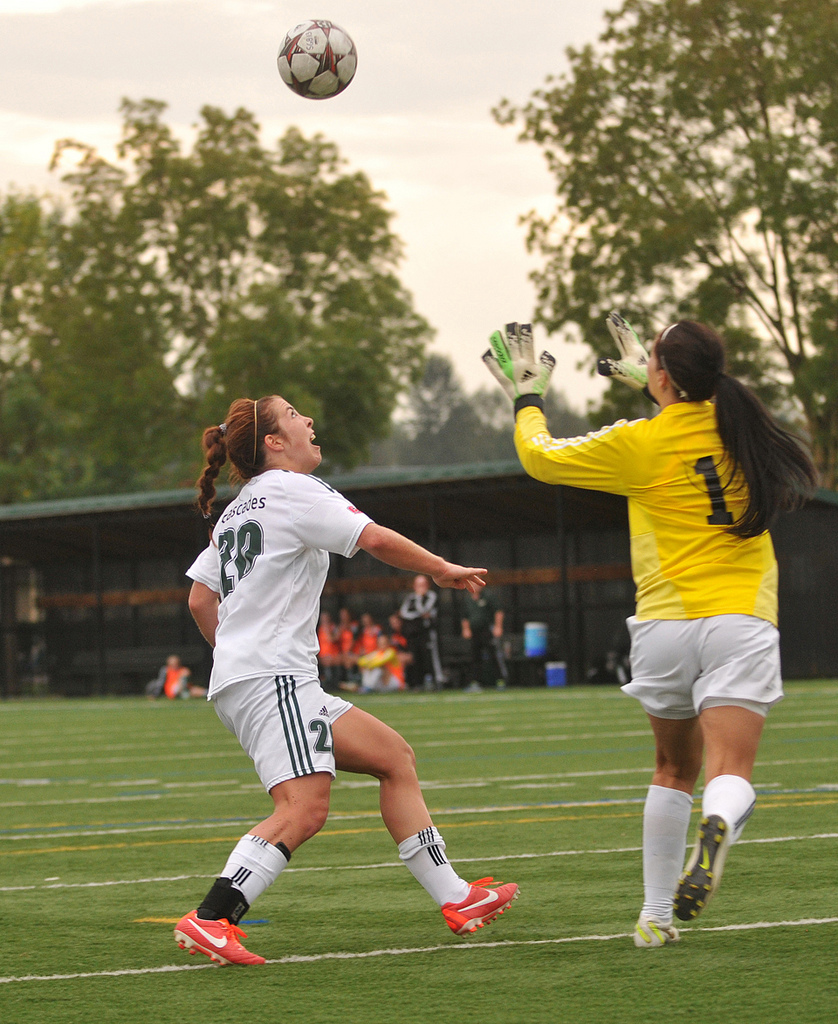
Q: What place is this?
A: It is a field.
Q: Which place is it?
A: It is a field.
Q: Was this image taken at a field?
A: Yes, it was taken in a field.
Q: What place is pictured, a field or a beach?
A: It is a field.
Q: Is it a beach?
A: No, it is a field.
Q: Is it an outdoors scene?
A: Yes, it is outdoors.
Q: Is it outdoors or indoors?
A: It is outdoors.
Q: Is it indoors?
A: No, it is outdoors.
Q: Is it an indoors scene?
A: No, it is outdoors.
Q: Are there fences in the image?
A: No, there are no fences.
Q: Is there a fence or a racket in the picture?
A: No, there are no fences or rackets.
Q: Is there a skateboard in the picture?
A: No, there are no skateboards.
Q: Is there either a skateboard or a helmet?
A: No, there are no skateboards or helmets.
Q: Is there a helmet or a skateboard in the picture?
A: No, there are no skateboards or helmets.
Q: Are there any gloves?
A: Yes, there are gloves.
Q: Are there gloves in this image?
A: Yes, there are gloves.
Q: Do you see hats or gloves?
A: Yes, there are gloves.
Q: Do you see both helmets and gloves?
A: No, there are gloves but no helmets.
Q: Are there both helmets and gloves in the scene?
A: No, there are gloves but no helmets.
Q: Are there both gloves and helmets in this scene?
A: No, there are gloves but no helmets.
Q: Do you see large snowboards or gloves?
A: Yes, there are large gloves.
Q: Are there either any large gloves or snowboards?
A: Yes, there are large gloves.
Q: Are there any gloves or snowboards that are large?
A: Yes, the gloves are large.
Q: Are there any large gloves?
A: Yes, there are large gloves.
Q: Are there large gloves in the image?
A: Yes, there are large gloves.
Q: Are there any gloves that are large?
A: Yes, there are gloves that are large.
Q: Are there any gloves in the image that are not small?
A: Yes, there are large gloves.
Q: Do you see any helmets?
A: No, there are no helmets.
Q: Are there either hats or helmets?
A: No, there are no helmets or hats.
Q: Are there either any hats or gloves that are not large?
A: No, there are gloves but they are large.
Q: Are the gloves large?
A: Yes, the gloves are large.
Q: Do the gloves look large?
A: Yes, the gloves are large.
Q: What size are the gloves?
A: The gloves are large.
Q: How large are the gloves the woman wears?
A: The gloves are large.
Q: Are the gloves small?
A: No, the gloves are large.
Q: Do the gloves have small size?
A: No, the gloves are large.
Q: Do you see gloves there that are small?
A: No, there are gloves but they are large.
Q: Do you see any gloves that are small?
A: No, there are gloves but they are large.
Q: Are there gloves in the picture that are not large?
A: No, there are gloves but they are large.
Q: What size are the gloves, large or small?
A: The gloves are large.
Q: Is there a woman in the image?
A: Yes, there is a woman.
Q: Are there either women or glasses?
A: Yes, there is a woman.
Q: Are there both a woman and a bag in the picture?
A: No, there is a woman but no bags.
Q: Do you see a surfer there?
A: No, there are no surfers.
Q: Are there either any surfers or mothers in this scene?
A: No, there are no surfers or mothers.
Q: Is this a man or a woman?
A: This is a woman.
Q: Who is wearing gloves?
A: The woman is wearing gloves.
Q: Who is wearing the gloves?
A: The woman is wearing gloves.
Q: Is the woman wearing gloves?
A: Yes, the woman is wearing gloves.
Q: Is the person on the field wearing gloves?
A: Yes, the woman is wearing gloves.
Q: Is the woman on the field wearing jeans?
A: No, the woman is wearing gloves.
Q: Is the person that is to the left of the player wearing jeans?
A: No, the woman is wearing gloves.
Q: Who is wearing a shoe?
A: The woman is wearing a shoe.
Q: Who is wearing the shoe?
A: The woman is wearing a shoe.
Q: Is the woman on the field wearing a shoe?
A: Yes, the woman is wearing a shoe.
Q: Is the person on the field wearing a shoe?
A: Yes, the woman is wearing a shoe.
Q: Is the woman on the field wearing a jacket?
A: No, the woman is wearing a shoe.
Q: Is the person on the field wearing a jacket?
A: No, the woman is wearing a shoe.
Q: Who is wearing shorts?
A: The woman is wearing shorts.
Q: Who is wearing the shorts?
A: The woman is wearing shorts.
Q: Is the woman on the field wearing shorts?
A: Yes, the woman is wearing shorts.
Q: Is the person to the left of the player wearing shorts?
A: Yes, the woman is wearing shorts.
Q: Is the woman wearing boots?
A: No, the woman is wearing shorts.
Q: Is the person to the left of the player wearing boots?
A: No, the woman is wearing shorts.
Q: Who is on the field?
A: The woman is on the field.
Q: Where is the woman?
A: The woman is on the field.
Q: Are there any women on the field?
A: Yes, there is a woman on the field.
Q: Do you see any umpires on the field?
A: No, there is a woman on the field.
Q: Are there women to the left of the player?
A: Yes, there is a woman to the left of the player.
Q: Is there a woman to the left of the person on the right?
A: Yes, there is a woman to the left of the player.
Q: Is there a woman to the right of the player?
A: No, the woman is to the left of the player.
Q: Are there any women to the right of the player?
A: No, the woman is to the left of the player.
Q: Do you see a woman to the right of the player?
A: No, the woman is to the left of the player.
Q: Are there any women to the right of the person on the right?
A: No, the woman is to the left of the player.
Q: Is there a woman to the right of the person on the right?
A: No, the woman is to the left of the player.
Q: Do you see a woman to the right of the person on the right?
A: No, the woman is to the left of the player.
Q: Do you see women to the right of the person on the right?
A: No, the woman is to the left of the player.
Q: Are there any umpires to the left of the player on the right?
A: No, there is a woman to the left of the player.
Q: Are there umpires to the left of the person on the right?
A: No, there is a woman to the left of the player.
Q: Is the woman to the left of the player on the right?
A: Yes, the woman is to the left of the player.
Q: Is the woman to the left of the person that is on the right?
A: Yes, the woman is to the left of the player.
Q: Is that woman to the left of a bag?
A: No, the woman is to the left of the player.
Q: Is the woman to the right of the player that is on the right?
A: No, the woman is to the left of the player.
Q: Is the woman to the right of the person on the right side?
A: No, the woman is to the left of the player.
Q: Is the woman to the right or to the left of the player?
A: The woman is to the left of the player.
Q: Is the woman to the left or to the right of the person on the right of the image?
A: The woman is to the left of the player.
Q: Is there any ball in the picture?
A: Yes, there is a ball.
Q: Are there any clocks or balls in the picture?
A: Yes, there is a ball.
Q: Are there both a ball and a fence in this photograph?
A: No, there is a ball but no fences.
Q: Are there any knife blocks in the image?
A: No, there are no knife blocks.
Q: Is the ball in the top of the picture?
A: Yes, the ball is in the top of the image.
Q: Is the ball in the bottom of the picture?
A: No, the ball is in the top of the image.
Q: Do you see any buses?
A: No, there are no buses.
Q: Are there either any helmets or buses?
A: No, there are no buses or helmets.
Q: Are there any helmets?
A: No, there are no helmets.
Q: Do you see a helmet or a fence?
A: No, there are no helmets or fences.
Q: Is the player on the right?
A: Yes, the player is on the right of the image.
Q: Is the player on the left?
A: No, the player is on the right of the image.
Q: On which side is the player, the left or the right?
A: The player is on the right of the image.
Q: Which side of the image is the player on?
A: The player is on the right of the image.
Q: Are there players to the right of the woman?
A: Yes, there is a player to the right of the woman.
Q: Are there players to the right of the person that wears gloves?
A: Yes, there is a player to the right of the woman.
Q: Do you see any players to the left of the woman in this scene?
A: No, the player is to the right of the woman.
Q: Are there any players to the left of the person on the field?
A: No, the player is to the right of the woman.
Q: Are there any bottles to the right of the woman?
A: No, there is a player to the right of the woman.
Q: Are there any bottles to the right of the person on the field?
A: No, there is a player to the right of the woman.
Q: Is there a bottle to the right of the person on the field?
A: No, there is a player to the right of the woman.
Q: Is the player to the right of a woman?
A: Yes, the player is to the right of a woman.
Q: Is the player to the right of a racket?
A: No, the player is to the right of a woman.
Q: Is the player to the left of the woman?
A: No, the player is to the right of the woman.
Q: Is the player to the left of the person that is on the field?
A: No, the player is to the right of the woman.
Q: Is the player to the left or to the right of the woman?
A: The player is to the right of the woman.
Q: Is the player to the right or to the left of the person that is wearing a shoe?
A: The player is to the right of the woman.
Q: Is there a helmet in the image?
A: No, there are no helmets.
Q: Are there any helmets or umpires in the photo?
A: No, there are no helmets or umpires.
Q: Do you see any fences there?
A: No, there are no fences.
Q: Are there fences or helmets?
A: No, there are no fences or helmets.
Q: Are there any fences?
A: No, there are no fences.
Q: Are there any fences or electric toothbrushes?
A: No, there are no fences or electric toothbrushes.